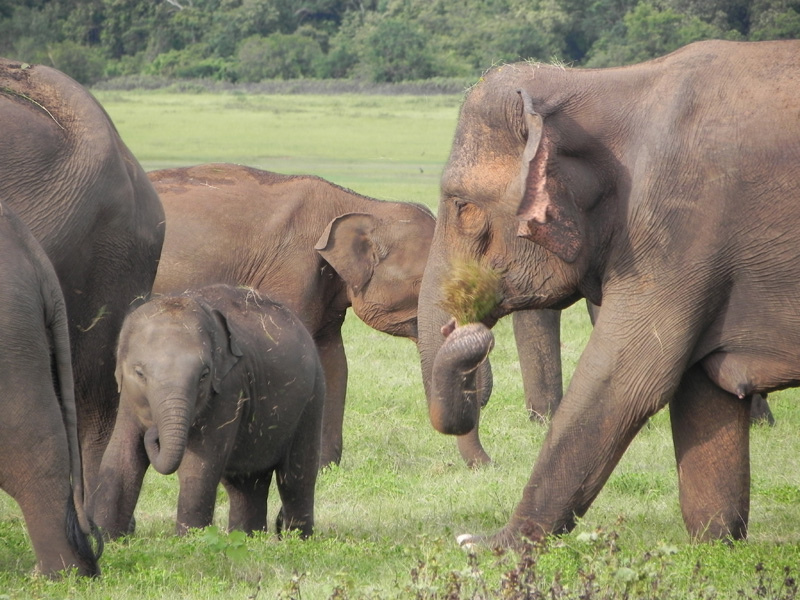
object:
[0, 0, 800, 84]
area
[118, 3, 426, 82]
trees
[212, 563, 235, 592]
patch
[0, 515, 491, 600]
ground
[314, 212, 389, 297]
ear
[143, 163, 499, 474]
elephant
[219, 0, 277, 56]
tree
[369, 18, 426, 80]
tree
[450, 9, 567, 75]
tree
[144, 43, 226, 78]
tree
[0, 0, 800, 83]
forest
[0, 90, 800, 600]
field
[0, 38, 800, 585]
elephants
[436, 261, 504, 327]
grass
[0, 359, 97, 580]
rear leg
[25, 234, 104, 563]
tail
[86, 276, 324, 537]
elephant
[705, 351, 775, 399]
breast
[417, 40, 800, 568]
elephant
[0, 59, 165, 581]
elephant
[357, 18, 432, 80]
bush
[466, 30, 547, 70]
bush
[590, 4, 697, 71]
bush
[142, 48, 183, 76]
bush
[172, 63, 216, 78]
bush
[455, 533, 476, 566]
flower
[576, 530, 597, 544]
flower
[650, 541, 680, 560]
flower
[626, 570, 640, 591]
flower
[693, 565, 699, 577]
flower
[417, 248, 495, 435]
trunk